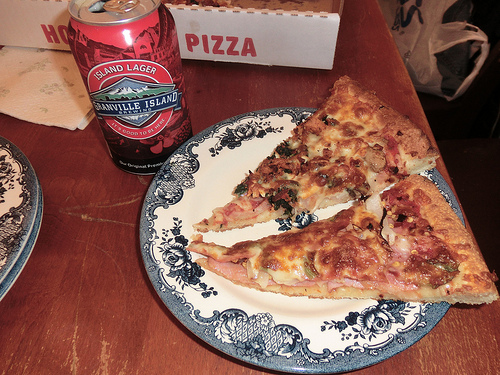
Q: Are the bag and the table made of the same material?
A: No, the bag is made of plastic and the table is made of wood.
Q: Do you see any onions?
A: Yes, there is an onion.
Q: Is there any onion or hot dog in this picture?
A: Yes, there is an onion.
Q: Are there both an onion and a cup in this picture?
A: No, there is an onion but no cups.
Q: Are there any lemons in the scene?
A: No, there are no lemons.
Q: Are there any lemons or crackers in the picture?
A: No, there are no lemons or crackers.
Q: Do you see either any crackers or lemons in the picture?
A: No, there are no lemons or crackers.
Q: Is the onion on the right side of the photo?
A: Yes, the onion is on the right of the image.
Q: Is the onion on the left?
A: No, the onion is on the right of the image.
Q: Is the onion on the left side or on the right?
A: The onion is on the right of the image.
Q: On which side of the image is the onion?
A: The onion is on the right of the image.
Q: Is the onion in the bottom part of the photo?
A: Yes, the onion is in the bottom of the image.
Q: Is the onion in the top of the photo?
A: No, the onion is in the bottom of the image.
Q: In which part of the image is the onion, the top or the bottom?
A: The onion is in the bottom of the image.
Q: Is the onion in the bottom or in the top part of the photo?
A: The onion is in the bottom of the image.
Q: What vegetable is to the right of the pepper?
A: The vegetable is an onion.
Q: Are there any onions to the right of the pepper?
A: Yes, there is an onion to the right of the pepper.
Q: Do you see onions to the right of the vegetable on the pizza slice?
A: Yes, there is an onion to the right of the pepper.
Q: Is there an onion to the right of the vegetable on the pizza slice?
A: Yes, there is an onion to the right of the pepper.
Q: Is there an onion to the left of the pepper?
A: No, the onion is to the right of the pepper.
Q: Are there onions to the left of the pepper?
A: No, the onion is to the right of the pepper.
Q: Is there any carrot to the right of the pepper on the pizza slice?
A: No, there is an onion to the right of the pepper.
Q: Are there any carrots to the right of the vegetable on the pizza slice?
A: No, there is an onion to the right of the pepper.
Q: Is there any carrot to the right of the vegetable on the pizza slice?
A: No, there is an onion to the right of the pepper.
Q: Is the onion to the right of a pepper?
A: Yes, the onion is to the right of a pepper.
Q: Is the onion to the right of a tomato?
A: No, the onion is to the right of a pepper.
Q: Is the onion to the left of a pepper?
A: No, the onion is to the right of a pepper.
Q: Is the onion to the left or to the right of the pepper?
A: The onion is to the right of the pepper.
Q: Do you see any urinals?
A: No, there are no urinals.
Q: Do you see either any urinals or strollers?
A: No, there are no urinals or strollers.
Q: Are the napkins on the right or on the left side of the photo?
A: The napkins are on the left of the image.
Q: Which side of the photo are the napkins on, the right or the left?
A: The napkins are on the left of the image.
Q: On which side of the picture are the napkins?
A: The napkins are on the left of the image.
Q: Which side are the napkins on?
A: The napkins are on the left of the image.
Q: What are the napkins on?
A: The napkins are on the table.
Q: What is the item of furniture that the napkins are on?
A: The piece of furniture is a table.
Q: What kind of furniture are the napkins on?
A: The napkins are on the table.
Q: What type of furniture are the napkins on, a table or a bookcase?
A: The napkins are on a table.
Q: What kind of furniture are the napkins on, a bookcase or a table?
A: The napkins are on a table.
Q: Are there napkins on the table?
A: Yes, there are napkins on the table.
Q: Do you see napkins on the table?
A: Yes, there are napkins on the table.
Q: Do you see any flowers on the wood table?
A: No, there are napkins on the table.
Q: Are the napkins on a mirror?
A: No, the napkins are on the table.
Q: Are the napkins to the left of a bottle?
A: No, the napkins are to the left of a pizza.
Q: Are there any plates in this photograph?
A: Yes, there is a plate.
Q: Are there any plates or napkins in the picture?
A: Yes, there is a plate.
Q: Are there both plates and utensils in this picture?
A: No, there is a plate but no utensils.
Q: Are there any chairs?
A: No, there are no chairs.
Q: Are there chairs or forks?
A: No, there are no chairs or forks.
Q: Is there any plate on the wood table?
A: Yes, there is a plate on the table.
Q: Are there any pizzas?
A: Yes, there is a pizza.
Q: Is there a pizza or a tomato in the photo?
A: Yes, there is a pizza.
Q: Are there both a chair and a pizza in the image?
A: No, there is a pizza but no chairs.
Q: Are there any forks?
A: No, there are no forks.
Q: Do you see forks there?
A: No, there are no forks.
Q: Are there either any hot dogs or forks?
A: No, there are no forks or hot dogs.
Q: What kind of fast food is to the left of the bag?
A: The food is a pizza.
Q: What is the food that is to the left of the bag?
A: The food is a pizza.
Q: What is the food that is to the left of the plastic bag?
A: The food is a pizza.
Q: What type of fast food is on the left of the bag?
A: The food is a pizza.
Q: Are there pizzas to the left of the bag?
A: Yes, there is a pizza to the left of the bag.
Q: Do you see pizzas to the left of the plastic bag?
A: Yes, there is a pizza to the left of the bag.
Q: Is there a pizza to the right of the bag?
A: No, the pizza is to the left of the bag.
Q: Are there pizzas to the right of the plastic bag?
A: No, the pizza is to the left of the bag.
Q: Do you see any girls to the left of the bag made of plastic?
A: No, there is a pizza to the left of the bag.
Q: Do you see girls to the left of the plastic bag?
A: No, there is a pizza to the left of the bag.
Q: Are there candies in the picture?
A: No, there are no candies.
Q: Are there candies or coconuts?
A: No, there are no candies or coconuts.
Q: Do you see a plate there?
A: Yes, there is a plate.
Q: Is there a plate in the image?
A: Yes, there is a plate.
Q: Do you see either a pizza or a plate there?
A: Yes, there is a plate.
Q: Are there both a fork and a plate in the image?
A: No, there is a plate but no forks.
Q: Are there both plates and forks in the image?
A: No, there is a plate but no forks.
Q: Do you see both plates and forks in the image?
A: No, there is a plate but no forks.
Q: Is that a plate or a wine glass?
A: That is a plate.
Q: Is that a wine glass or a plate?
A: That is a plate.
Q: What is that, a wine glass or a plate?
A: That is a plate.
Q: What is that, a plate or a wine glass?
A: That is a plate.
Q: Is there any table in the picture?
A: Yes, there is a table.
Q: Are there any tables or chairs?
A: Yes, there is a table.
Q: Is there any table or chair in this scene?
A: Yes, there is a table.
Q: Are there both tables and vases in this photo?
A: No, there is a table but no vases.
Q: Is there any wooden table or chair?
A: Yes, there is a wood table.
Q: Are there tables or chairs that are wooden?
A: Yes, the table is wooden.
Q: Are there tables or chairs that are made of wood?
A: Yes, the table is made of wood.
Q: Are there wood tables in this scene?
A: Yes, there is a wood table.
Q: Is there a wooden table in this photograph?
A: Yes, there is a wood table.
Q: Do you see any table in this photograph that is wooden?
A: Yes, there is a table that is wooden.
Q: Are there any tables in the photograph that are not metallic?
A: Yes, there is a wooden table.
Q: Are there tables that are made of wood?
A: Yes, there is a table that is made of wood.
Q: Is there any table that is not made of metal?
A: Yes, there is a table that is made of wood.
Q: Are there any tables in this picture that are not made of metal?
A: Yes, there is a table that is made of wood.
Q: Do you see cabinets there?
A: No, there are no cabinets.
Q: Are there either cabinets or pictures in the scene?
A: No, there are no cabinets or pictures.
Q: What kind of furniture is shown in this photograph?
A: The furniture is a table.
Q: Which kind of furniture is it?
A: The piece of furniture is a table.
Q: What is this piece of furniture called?
A: That is a table.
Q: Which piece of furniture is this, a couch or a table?
A: That is a table.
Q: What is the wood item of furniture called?
A: The piece of furniture is a table.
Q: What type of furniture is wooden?
A: The furniture is a table.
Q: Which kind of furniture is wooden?
A: The furniture is a table.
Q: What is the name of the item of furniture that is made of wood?
A: The piece of furniture is a table.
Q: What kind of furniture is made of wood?
A: The furniture is a table.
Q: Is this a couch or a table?
A: This is a table.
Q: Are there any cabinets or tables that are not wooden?
A: No, there is a table but it is wooden.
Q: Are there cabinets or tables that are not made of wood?
A: No, there is a table but it is made of wood.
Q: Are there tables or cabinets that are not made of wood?
A: No, there is a table but it is made of wood.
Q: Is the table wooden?
A: Yes, the table is wooden.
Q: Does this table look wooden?
A: Yes, the table is wooden.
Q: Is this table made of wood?
A: Yes, the table is made of wood.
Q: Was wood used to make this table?
A: Yes, the table is made of wood.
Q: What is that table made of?
A: The table is made of wood.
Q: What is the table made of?
A: The table is made of wood.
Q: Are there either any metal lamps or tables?
A: No, there is a table but it is wooden.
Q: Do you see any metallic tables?
A: No, there is a table but it is wooden.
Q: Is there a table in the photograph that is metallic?
A: No, there is a table but it is wooden.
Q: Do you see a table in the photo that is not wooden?
A: No, there is a table but it is wooden.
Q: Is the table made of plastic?
A: No, the table is made of wood.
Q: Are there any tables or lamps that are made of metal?
A: No, there is a table but it is made of wood.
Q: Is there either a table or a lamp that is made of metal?
A: No, there is a table but it is made of wood.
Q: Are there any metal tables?
A: No, there is a table but it is made of wood.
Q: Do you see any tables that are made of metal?
A: No, there is a table but it is made of wood.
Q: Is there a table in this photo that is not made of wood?
A: No, there is a table but it is made of wood.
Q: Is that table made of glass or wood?
A: The table is made of wood.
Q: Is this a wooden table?
A: Yes, this is a wooden table.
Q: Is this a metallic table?
A: No, this is a wooden table.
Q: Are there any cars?
A: No, there are no cars.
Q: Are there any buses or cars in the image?
A: No, there are no cars or buses.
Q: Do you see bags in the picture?
A: Yes, there is a bag.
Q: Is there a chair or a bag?
A: Yes, there is a bag.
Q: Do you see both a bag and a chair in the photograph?
A: No, there is a bag but no chairs.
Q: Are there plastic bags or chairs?
A: Yes, there is a plastic bag.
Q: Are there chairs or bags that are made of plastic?
A: Yes, the bag is made of plastic.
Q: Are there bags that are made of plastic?
A: Yes, there is a bag that is made of plastic.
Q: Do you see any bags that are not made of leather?
A: Yes, there is a bag that is made of plastic.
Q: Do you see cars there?
A: No, there are no cars.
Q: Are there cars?
A: No, there are no cars.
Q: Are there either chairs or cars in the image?
A: No, there are no cars or chairs.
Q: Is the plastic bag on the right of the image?
A: Yes, the bag is on the right of the image.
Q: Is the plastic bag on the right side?
A: Yes, the bag is on the right of the image.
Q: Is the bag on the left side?
A: No, the bag is on the right of the image.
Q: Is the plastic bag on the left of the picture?
A: No, the bag is on the right of the image.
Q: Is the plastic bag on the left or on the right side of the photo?
A: The bag is on the right of the image.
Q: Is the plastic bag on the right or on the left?
A: The bag is on the right of the image.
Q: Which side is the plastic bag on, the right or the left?
A: The bag is on the right of the image.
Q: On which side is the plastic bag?
A: The bag is on the right of the image.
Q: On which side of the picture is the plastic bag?
A: The bag is on the right of the image.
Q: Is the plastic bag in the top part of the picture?
A: Yes, the bag is in the top of the image.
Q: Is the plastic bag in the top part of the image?
A: Yes, the bag is in the top of the image.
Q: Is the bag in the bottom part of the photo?
A: No, the bag is in the top of the image.